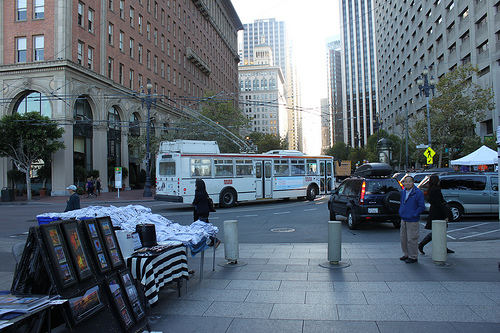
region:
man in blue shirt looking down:
[400, 171, 422, 264]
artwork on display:
[13, 216, 151, 331]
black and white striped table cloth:
[127, 241, 193, 308]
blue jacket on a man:
[400, 187, 425, 220]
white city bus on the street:
[157, 149, 337, 201]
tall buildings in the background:
[0, 1, 289, 193]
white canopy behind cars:
[447, 141, 498, 164]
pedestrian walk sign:
[419, 144, 436, 164]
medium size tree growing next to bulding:
[4, 111, 61, 206]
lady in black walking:
[419, 171, 452, 260]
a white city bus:
[146, 133, 347, 217]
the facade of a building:
[372, 2, 498, 138]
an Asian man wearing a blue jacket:
[391, 172, 431, 272]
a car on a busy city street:
[324, 162, 404, 234]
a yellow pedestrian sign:
[421, 143, 438, 170]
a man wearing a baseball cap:
[58, 179, 80, 216]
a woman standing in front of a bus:
[150, 136, 218, 224]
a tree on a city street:
[0, 97, 61, 197]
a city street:
[223, 194, 350, 246]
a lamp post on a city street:
[409, 64, 436, 129]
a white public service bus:
[155, 140, 337, 207]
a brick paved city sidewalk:
[153, 234, 495, 331]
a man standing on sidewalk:
[395, 170, 421, 261]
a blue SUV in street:
[327, 177, 407, 231]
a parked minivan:
[413, 173, 498, 221]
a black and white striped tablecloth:
[128, 239, 192, 306]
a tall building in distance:
[238, 58, 287, 143]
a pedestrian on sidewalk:
[190, 175, 221, 250]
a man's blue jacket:
[399, 185, 424, 222]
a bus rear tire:
[218, 185, 238, 210]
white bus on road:
[152, 147, 334, 209]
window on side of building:
[116, 63, 127, 85]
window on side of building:
[458, 28, 469, 43]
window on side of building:
[394, 91, 401, 108]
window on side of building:
[33, 36, 41, 58]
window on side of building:
[11, 38, 26, 60]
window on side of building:
[33, 0, 45, 20]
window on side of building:
[7, 0, 24, 21]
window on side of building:
[78, 3, 83, 25]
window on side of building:
[71, 38, 83, 65]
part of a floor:
[295, 262, 315, 277]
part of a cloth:
[147, 250, 202, 295]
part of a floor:
[276, 285, 302, 322]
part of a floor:
[266, 283, 289, 312]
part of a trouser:
[396, 220, 417, 244]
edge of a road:
[279, 229, 304, 244]